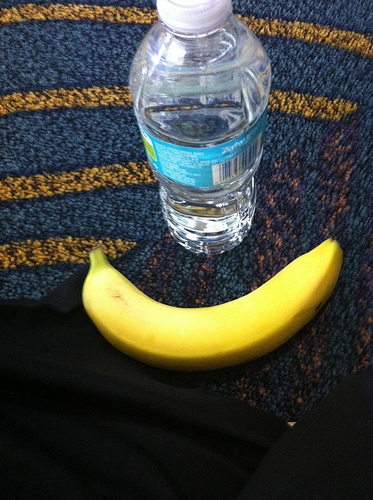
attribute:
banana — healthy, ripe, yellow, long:
[80, 236, 343, 373]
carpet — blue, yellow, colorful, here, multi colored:
[2, 1, 372, 419]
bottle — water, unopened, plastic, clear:
[127, 1, 273, 265]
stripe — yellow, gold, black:
[0, 160, 157, 201]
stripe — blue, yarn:
[0, 185, 172, 246]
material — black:
[3, 263, 370, 499]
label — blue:
[132, 108, 271, 193]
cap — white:
[154, 0, 233, 35]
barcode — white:
[211, 131, 265, 187]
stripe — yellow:
[4, 233, 137, 268]